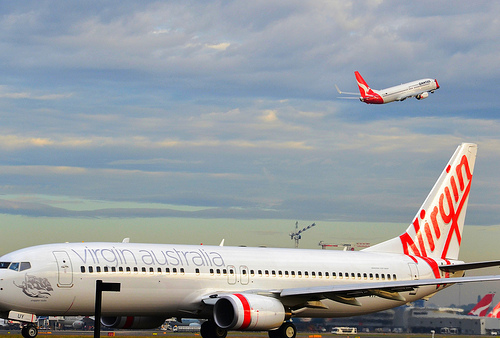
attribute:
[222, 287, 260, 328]
stripe — circular, red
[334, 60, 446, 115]
aircraft — departing, taking off, red, white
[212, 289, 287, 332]
engine — white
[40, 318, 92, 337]
open space — behind wheel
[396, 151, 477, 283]
virgin — red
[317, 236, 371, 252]
crane — large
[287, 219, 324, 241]
post — black, white, striped